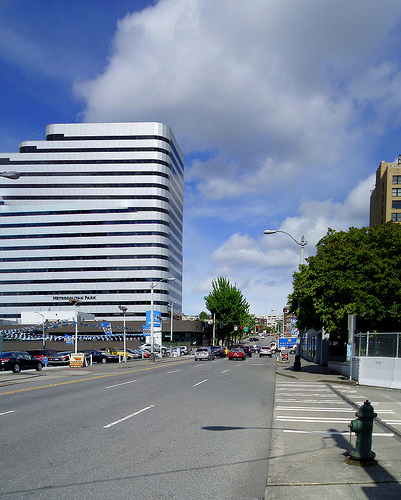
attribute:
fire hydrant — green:
[349, 396, 381, 458]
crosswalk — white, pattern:
[278, 373, 365, 434]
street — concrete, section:
[90, 377, 374, 442]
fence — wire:
[337, 331, 400, 374]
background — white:
[1, 69, 401, 383]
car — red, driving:
[227, 344, 243, 366]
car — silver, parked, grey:
[196, 348, 217, 360]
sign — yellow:
[73, 351, 87, 370]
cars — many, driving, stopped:
[196, 348, 271, 372]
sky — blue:
[35, 14, 399, 134]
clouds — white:
[189, 10, 355, 132]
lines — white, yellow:
[55, 366, 157, 434]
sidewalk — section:
[266, 353, 399, 498]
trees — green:
[215, 221, 397, 332]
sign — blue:
[278, 335, 299, 351]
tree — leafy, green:
[285, 247, 401, 324]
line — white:
[101, 390, 166, 446]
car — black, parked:
[1, 348, 44, 380]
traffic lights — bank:
[225, 329, 287, 343]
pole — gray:
[293, 247, 310, 261]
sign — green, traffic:
[242, 323, 256, 335]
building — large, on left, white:
[1, 133, 194, 313]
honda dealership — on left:
[4, 117, 190, 372]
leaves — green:
[353, 253, 367, 273]